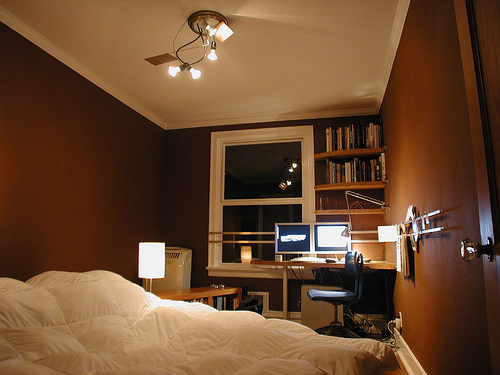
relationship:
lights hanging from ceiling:
[133, 18, 242, 94] [161, 87, 303, 121]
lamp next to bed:
[134, 235, 168, 292] [1, 267, 428, 374]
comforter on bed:
[1, 267, 401, 374] [1, 267, 428, 374]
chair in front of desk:
[306, 251, 364, 339] [258, 249, 388, 286]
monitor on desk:
[277, 223, 311, 252] [206, 260, 396, 322]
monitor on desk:
[315, 224, 349, 251] [206, 260, 396, 322]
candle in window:
[240, 246, 252, 264] [222, 137, 303, 262]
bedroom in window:
[0, 0, 499, 375] [213, 135, 308, 267]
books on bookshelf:
[308, 126, 392, 187] [322, 149, 382, 160]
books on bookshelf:
[308, 126, 392, 187] [315, 179, 382, 191]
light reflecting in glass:
[271, 153, 301, 195] [221, 140, 299, 260]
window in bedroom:
[206, 130, 327, 295] [0, 0, 499, 375]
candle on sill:
[240, 249, 249, 262] [213, 252, 298, 288]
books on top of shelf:
[320, 118, 391, 153] [315, 126, 387, 154]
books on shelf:
[317, 144, 392, 192] [320, 178, 380, 191]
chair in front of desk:
[306, 248, 369, 343] [270, 258, 349, 270]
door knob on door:
[459, 238, 478, 263] [369, 4, 496, 365]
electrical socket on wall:
[392, 309, 404, 331] [377, 0, 498, 372]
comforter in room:
[1, 270, 398, 375] [4, 2, 494, 374]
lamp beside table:
[138, 241, 165, 292] [156, 285, 237, 304]